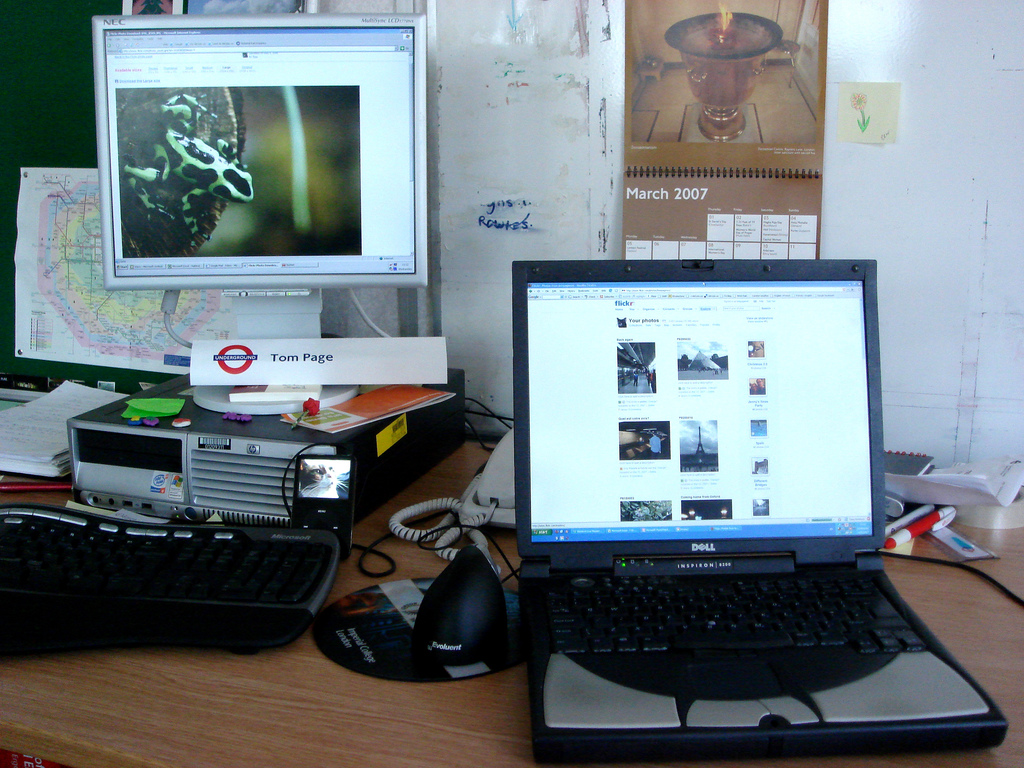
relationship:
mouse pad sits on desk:
[317, 570, 529, 694] [6, 427, 1009, 765]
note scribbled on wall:
[475, 198, 542, 244] [112, 3, 1009, 475]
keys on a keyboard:
[65, 544, 150, 592] [0, 507, 342, 687]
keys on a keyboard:
[605, 602, 668, 648] [536, 556, 999, 708]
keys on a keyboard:
[24, 541, 107, 587] [6, 515, 335, 660]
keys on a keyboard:
[792, 600, 851, 644] [536, 565, 936, 667]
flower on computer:
[289, 378, 331, 430] [41, 4, 461, 549]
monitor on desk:
[509, 259, 892, 569] [0, 408, 1024, 768]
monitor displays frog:
[82, 52, 437, 297] [130, 93, 258, 249]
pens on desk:
[882, 479, 962, 577] [426, 472, 1010, 766]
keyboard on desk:
[20, 531, 316, 650] [4, 654, 419, 768]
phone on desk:
[437, 445, 505, 573] [216, 641, 515, 768]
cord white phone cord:
[388, 490, 497, 560] [413, 490, 453, 551]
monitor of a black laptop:
[509, 259, 892, 569] [575, 371, 746, 478]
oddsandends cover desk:
[6, 467, 531, 675] [43, 408, 903, 705]